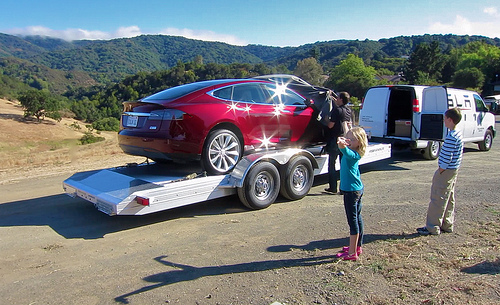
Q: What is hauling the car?
A: A white trailer.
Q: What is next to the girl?
A: A red car.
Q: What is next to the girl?
A: Her shadow.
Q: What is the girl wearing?
A: A blue shirt.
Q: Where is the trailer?
A: On a dirt road.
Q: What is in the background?
A: A green hill.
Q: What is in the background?
A: Green trees.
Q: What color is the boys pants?
A: Khaki.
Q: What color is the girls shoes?
A: Pink.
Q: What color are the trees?
A: Green.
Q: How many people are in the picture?
A: Three.